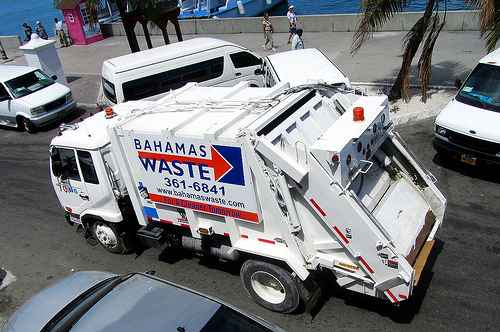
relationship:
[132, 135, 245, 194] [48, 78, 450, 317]
logo on truck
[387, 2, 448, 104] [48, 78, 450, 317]
palm by truck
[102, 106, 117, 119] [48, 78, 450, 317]
signal on truck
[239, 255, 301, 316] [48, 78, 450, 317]
wheel on truck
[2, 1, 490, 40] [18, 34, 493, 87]
water next to sidewalk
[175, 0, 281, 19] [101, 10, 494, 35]
boat by wall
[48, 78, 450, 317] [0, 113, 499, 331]
truck in street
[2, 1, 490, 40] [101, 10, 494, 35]
water behind wall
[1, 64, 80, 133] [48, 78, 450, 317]
van by truck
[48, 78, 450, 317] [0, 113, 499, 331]
truck on street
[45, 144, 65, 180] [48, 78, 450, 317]
mirror on truck